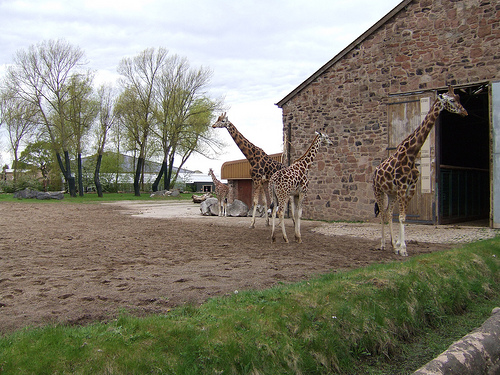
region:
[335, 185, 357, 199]
a brick on the wall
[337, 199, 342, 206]
a brick on the wall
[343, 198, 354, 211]
a brick on the wall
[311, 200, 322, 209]
a brick on the wall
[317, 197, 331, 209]
a brick on the wall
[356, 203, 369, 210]
a brick on the wall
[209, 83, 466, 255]
Girafffes in an enclosure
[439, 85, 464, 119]
The head of a giraffe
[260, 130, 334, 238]
A young giraffe on dirt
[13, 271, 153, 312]
Footprints in the dirt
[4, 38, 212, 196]
A grove of trees in an enclosure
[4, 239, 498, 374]
Grass growing along an enclosure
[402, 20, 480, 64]
Rocks in the wall of a building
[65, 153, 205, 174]
A roof on a building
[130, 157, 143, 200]
A dark brown tree trunk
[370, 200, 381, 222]
Black tufted tail on a giraffe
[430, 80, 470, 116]
face of a giraffe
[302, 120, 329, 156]
face of a giraffe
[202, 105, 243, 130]
face of a giraffe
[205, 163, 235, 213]
giraffe near a building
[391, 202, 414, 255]
leg of a giraffe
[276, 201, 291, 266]
leg of a giraffe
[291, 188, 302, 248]
leg of a giraffe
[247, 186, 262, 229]
leg of a giraffe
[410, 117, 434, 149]
neck of a giraffe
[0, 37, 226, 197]
a group of thin trees in the distance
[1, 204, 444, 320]
section of brown dirt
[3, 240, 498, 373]
section of green grass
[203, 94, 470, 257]
giraffes standing around in an enclosure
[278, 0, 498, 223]
a brick barn house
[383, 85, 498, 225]
opened door to the barn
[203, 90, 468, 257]
four giraffes gathered together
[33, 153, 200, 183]
building seen beyond the trees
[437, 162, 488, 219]
railing inside the barn house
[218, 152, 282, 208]
a shed beside the barn house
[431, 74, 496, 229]
open door of a barn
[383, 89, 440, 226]
wooden door of a barn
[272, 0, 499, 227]
big brick barn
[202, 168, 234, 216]
small giraffe near grey rocks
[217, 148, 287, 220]
small buiding attached to barn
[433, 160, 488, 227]
green wall inside barn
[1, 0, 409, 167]
clear white sky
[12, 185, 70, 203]
log in the grass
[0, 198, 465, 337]
brown dirt near the barn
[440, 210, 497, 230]
floor in the barn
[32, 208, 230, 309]
the field is bare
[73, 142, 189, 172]
mountain in the distance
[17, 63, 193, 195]
mountain behind the trees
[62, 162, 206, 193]
building behind the trees